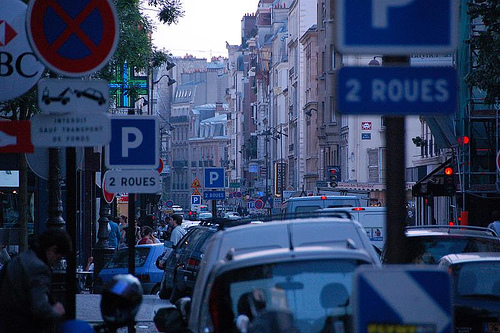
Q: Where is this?
A: This is at the road.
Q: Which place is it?
A: It is a road.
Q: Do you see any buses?
A: No, there are no buses.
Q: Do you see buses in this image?
A: No, there are no buses.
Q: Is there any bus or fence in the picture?
A: No, there are no buses or fences.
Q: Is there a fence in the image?
A: No, there are no fences.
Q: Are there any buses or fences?
A: No, there are no fences or buses.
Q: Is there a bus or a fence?
A: No, there are no fences or buses.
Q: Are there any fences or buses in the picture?
A: No, there are no fences or buses.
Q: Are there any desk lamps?
A: No, there are no desk lamps.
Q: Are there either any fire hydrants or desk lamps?
A: No, there are no desk lamps or fire hydrants.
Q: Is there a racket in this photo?
A: No, there are no rackets.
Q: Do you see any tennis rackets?
A: No, there are no tennis rackets.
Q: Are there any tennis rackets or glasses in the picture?
A: No, there are no tennis rackets or glasses.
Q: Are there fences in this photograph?
A: No, there are no fences.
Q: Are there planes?
A: No, there are no planes.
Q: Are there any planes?
A: No, there are no planes.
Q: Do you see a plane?
A: No, there are no airplanes.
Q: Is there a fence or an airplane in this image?
A: No, there are no airplanes or fences.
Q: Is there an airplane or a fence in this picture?
A: No, there are no airplanes or fences.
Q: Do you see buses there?
A: No, there are no buses.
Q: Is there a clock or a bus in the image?
A: No, there are no buses or clocks.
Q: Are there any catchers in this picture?
A: No, there are no catchers.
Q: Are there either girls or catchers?
A: No, there are no catchers or girls.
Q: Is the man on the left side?
A: Yes, the man is on the left of the image.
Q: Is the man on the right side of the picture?
A: No, the man is on the left of the image.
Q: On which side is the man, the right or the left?
A: The man is on the left of the image.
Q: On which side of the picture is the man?
A: The man is on the left of the image.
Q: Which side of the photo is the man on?
A: The man is on the left of the image.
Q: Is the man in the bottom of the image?
A: Yes, the man is in the bottom of the image.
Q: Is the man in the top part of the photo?
A: No, the man is in the bottom of the image.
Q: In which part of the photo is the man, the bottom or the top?
A: The man is in the bottom of the image.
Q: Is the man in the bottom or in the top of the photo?
A: The man is in the bottom of the image.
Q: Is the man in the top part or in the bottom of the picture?
A: The man is in the bottom of the image.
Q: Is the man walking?
A: Yes, the man is walking.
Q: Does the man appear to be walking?
A: Yes, the man is walking.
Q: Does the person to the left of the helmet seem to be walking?
A: Yes, the man is walking.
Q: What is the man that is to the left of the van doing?
A: The man is walking.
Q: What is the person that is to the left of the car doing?
A: The man is walking.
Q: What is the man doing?
A: The man is walking.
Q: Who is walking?
A: The man is walking.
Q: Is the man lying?
A: No, the man is walking.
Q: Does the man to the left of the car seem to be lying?
A: No, the man is walking.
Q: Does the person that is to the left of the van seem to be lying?
A: No, the man is walking.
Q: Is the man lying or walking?
A: The man is walking.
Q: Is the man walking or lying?
A: The man is walking.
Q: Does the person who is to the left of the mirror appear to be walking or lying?
A: The man is walking.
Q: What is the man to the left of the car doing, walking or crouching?
A: The man is walking.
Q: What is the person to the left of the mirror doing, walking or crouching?
A: The man is walking.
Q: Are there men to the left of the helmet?
A: Yes, there is a man to the left of the helmet.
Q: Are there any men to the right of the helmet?
A: No, the man is to the left of the helmet.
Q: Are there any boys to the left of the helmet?
A: No, there is a man to the left of the helmet.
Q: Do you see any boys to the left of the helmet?
A: No, there is a man to the left of the helmet.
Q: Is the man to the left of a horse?
A: No, the man is to the left of the helmet.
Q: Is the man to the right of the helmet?
A: No, the man is to the left of the helmet.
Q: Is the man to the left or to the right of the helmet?
A: The man is to the left of the helmet.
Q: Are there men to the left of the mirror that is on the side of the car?
A: Yes, there is a man to the left of the mirror.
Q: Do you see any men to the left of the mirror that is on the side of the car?
A: Yes, there is a man to the left of the mirror.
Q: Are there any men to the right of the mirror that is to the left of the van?
A: No, the man is to the left of the mirror.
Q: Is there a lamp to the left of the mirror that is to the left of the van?
A: No, there is a man to the left of the mirror.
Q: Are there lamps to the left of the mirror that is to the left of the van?
A: No, there is a man to the left of the mirror.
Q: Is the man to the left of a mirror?
A: Yes, the man is to the left of a mirror.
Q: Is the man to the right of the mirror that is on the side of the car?
A: No, the man is to the left of the mirror.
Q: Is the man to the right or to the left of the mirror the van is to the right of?
A: The man is to the left of the mirror.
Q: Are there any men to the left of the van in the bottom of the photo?
A: Yes, there is a man to the left of the van.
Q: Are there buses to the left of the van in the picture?
A: No, there is a man to the left of the van.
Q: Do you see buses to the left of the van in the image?
A: No, there is a man to the left of the van.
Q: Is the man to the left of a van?
A: Yes, the man is to the left of a van.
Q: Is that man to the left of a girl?
A: No, the man is to the left of a van.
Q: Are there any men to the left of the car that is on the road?
A: Yes, there is a man to the left of the car.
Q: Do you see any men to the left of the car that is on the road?
A: Yes, there is a man to the left of the car.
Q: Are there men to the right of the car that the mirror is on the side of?
A: No, the man is to the left of the car.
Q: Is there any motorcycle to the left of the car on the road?
A: No, there is a man to the left of the car.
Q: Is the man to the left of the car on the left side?
A: Yes, the man is to the left of the car.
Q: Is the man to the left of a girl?
A: No, the man is to the left of the car.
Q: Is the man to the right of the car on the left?
A: No, the man is to the left of the car.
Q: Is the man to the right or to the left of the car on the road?
A: The man is to the left of the car.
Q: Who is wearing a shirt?
A: The man is wearing a shirt.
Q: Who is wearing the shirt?
A: The man is wearing a shirt.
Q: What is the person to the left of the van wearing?
A: The man is wearing a shirt.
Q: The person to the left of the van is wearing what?
A: The man is wearing a shirt.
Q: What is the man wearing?
A: The man is wearing a shirt.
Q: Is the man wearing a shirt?
A: Yes, the man is wearing a shirt.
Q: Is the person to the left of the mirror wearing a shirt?
A: Yes, the man is wearing a shirt.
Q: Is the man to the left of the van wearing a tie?
A: No, the man is wearing a shirt.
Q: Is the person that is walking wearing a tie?
A: No, the man is wearing a shirt.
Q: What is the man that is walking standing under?
A: The man is standing under the sign.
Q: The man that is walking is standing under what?
A: The man is standing under the sign.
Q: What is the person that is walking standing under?
A: The man is standing under the sign.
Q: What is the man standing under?
A: The man is standing under the sign.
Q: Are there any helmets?
A: Yes, there is a helmet.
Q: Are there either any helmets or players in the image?
A: Yes, there is a helmet.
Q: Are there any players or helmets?
A: Yes, there is a helmet.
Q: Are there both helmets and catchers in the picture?
A: No, there is a helmet but no catchers.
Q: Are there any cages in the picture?
A: No, there are no cages.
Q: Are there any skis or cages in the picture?
A: No, there are no cages or skis.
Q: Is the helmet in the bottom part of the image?
A: Yes, the helmet is in the bottom of the image.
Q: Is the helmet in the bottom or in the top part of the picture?
A: The helmet is in the bottom of the image.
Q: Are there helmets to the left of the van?
A: Yes, there is a helmet to the left of the van.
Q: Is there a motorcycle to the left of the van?
A: No, there is a helmet to the left of the van.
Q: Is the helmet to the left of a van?
A: Yes, the helmet is to the left of a van.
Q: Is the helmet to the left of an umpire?
A: No, the helmet is to the left of a van.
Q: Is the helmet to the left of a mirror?
A: Yes, the helmet is to the left of a mirror.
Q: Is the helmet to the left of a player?
A: No, the helmet is to the left of a mirror.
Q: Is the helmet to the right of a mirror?
A: No, the helmet is to the left of a mirror.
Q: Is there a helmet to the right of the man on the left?
A: Yes, there is a helmet to the right of the man.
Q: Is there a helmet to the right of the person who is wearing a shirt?
A: Yes, there is a helmet to the right of the man.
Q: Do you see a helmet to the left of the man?
A: No, the helmet is to the right of the man.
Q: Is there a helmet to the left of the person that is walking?
A: No, the helmet is to the right of the man.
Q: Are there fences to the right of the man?
A: No, there is a helmet to the right of the man.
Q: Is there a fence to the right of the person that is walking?
A: No, there is a helmet to the right of the man.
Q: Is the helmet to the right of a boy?
A: No, the helmet is to the right of the man.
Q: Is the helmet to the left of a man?
A: No, the helmet is to the right of a man.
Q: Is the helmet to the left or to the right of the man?
A: The helmet is to the right of the man.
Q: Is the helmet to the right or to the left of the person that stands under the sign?
A: The helmet is to the right of the man.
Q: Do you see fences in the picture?
A: No, there are no fences.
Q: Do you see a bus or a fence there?
A: No, there are no fences or buses.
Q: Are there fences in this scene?
A: No, there are no fences.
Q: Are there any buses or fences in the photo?
A: No, there are no fences or buses.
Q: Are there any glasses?
A: No, there are no glasses.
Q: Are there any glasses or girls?
A: No, there are no glasses or girls.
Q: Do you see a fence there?
A: No, there are no fences.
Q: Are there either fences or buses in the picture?
A: No, there are no fences or buses.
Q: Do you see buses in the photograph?
A: No, there are no buses.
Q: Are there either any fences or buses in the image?
A: No, there are no buses or fences.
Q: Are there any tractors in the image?
A: No, there are no tractors.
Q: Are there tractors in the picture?
A: No, there are no tractors.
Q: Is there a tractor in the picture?
A: No, there are no tractors.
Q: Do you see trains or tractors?
A: No, there are no tractors or trains.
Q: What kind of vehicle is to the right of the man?
A: The vehicle is a car.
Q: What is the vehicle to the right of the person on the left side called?
A: The vehicle is a car.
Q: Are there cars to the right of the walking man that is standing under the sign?
A: Yes, there is a car to the right of the man.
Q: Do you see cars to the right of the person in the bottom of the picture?
A: Yes, there is a car to the right of the man.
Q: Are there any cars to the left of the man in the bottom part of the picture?
A: No, the car is to the right of the man.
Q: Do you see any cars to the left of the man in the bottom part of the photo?
A: No, the car is to the right of the man.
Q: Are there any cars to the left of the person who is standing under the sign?
A: No, the car is to the right of the man.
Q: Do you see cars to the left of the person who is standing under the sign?
A: No, the car is to the right of the man.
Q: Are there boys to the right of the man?
A: No, there is a car to the right of the man.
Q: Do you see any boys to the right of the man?
A: No, there is a car to the right of the man.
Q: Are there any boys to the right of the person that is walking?
A: No, there is a car to the right of the man.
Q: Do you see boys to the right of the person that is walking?
A: No, there is a car to the right of the man.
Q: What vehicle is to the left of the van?
A: The vehicle is a car.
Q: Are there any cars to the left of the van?
A: Yes, there is a car to the left of the van.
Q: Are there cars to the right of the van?
A: No, the car is to the left of the van.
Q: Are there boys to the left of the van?
A: No, there is a car to the left of the van.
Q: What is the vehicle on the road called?
A: The vehicle is a car.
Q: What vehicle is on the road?
A: The vehicle is a car.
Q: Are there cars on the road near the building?
A: Yes, there is a car on the road.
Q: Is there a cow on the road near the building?
A: No, there is a car on the road.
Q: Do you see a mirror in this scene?
A: Yes, there is a mirror.